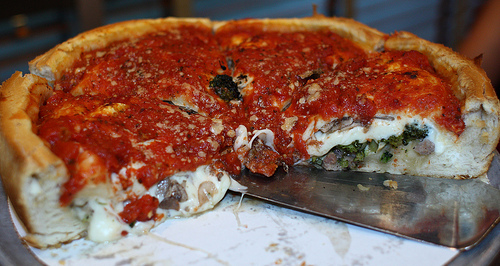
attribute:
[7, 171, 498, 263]
plate — paper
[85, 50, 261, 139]
seasoning — Italian 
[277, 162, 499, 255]
spatula — silver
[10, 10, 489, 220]
pizza — pepperoni, half , spinach , thick, deep dish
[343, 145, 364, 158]
broccoli — green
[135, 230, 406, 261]
plate — paper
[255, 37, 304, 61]
sauce — red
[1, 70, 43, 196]
crust — brown, thick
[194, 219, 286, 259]
cardboard — white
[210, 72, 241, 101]
food item — green